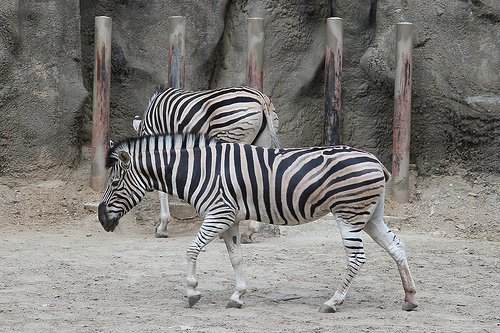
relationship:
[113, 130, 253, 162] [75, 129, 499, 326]
mane on zebra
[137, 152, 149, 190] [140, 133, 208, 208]
stripe on neck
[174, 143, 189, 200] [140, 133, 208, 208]
stripe on neck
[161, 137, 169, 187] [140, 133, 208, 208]
stripe on neck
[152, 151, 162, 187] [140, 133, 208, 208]
stripe on neck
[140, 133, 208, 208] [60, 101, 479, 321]
neck on zebra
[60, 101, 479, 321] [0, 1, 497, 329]
zebra in enclosure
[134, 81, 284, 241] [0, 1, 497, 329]
zebra in enclosure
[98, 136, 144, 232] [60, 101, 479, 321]
head on zebra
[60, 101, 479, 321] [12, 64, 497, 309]
zebra in enclosure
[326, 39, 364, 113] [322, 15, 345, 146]
paint on pole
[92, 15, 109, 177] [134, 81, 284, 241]
grey pole by zebra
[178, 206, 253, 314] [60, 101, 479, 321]
legs on zebra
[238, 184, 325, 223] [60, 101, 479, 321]
stripes on zebra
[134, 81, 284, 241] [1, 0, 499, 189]
zebra by wall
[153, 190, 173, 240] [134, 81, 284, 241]
leg on zebra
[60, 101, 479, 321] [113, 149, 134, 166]
zebra has ear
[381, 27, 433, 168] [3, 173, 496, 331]
pole in ground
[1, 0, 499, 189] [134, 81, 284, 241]
wall behind zebra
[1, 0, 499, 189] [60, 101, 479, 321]
wall behind zebra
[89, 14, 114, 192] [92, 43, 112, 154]
grey pole has marking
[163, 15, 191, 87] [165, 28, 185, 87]
pole has marking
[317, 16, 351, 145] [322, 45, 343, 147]
pole has paint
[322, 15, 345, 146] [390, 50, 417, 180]
pole has marking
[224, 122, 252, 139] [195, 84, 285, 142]
lines are on rear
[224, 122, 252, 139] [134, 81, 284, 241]
lines are on zebra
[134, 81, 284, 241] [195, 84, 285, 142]
zebra has rear